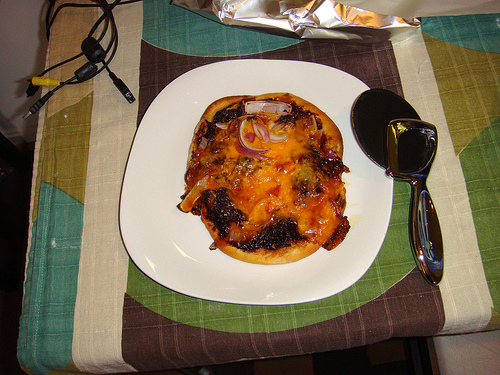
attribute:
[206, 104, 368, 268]
pizza — small, round, burnt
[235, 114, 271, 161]
onion — red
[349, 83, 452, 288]
pizza cutter — round, shiny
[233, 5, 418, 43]
foil — silver, shiny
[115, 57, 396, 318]
plate — white, squared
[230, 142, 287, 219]
cheese — orange, melted, burnt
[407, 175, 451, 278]
handle — brown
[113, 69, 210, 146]
edges — round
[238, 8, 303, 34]
foil — wrinkled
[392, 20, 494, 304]
stripe — thick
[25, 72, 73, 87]
cover — yellow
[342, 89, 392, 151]
blade — round